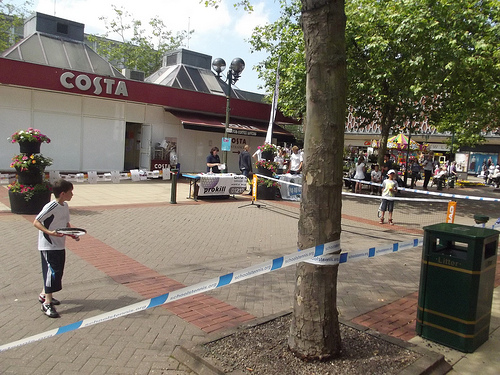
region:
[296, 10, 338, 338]
the trunk of the tree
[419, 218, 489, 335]
a green trash can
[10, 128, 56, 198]
flowers in pots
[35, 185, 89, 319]
a kid holding a frisbee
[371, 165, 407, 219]
a kid in a white hat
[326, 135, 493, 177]
people standing by the building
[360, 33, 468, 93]
leaves on the tree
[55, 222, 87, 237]
a white frisbee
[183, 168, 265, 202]
a blue table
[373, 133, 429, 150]
an umbrella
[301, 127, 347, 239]
a tree log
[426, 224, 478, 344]
a trashcan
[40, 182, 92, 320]
a boy walking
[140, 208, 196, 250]
the ground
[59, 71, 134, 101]
writing on the building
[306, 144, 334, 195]
bark on the tree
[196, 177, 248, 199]
a banner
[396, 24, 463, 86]
green leaves on the tree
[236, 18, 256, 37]
clouds in the sky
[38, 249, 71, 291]
blue shorts the boy is wearing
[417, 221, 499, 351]
outdoor metal trash receptacle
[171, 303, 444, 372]
tree well formed by cement bricks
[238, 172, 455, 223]
tennis net set up on portable supports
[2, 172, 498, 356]
temporary outdoor tennis court on brick plaza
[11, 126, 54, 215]
tiered outdoor flower planter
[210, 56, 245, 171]
two large outdoor globe lights on metal pole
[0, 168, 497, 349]
two young boys playing tennis on a makeshift tennis court in outdoor shopping mall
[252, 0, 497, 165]
large tree in full leaf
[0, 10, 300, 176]
restaurant with entry blocked by construction work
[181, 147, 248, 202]
table set up by makeshift tennis court for sponsor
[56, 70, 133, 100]
this is a sign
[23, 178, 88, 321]
this is a little boy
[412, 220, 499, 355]
this is a trash can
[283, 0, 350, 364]
this is a tree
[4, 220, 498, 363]
this is blue and white tape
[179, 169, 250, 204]
this is a table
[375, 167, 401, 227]
this is a small boy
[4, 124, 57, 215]
this is a flower pot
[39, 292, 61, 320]
these are his shoes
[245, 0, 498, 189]
this is a green tree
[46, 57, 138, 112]
costa sign is on the building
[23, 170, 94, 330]
boy is holding a frisbee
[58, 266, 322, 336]
blue and white striped tape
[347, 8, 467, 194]
a very large tree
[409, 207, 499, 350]
a green trashcan with gold stripes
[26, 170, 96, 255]
boy is wearing white shirt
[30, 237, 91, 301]
Boy is wearing black shorts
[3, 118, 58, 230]
a 3 tiered plant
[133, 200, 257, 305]
a paved brick ground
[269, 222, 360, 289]
blue and white tape on a tree